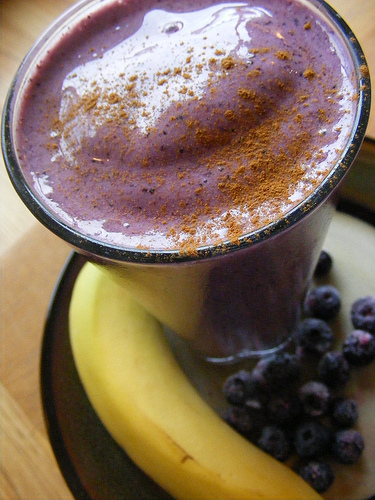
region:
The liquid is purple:
[8, 1, 357, 357]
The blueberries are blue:
[233, 257, 372, 481]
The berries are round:
[222, 250, 372, 488]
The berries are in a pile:
[223, 253, 371, 480]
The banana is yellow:
[65, 255, 317, 494]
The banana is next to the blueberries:
[69, 255, 364, 493]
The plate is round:
[49, 133, 370, 498]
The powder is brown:
[59, 40, 358, 238]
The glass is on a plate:
[6, 4, 359, 496]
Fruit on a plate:
[48, 157, 367, 492]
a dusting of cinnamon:
[186, 77, 297, 214]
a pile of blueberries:
[222, 352, 368, 493]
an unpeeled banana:
[64, 260, 310, 498]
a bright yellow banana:
[63, 258, 320, 499]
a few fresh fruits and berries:
[74, 260, 368, 497]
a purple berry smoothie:
[13, 2, 371, 352]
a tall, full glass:
[0, 0, 372, 356]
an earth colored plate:
[38, 201, 370, 497]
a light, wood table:
[1, 188, 64, 493]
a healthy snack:
[40, 31, 361, 486]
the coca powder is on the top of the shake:
[236, 154, 290, 202]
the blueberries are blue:
[256, 357, 306, 407]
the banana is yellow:
[117, 361, 168, 423]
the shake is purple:
[122, 33, 163, 64]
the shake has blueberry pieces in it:
[128, 174, 165, 200]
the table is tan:
[2, 389, 33, 437]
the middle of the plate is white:
[338, 226, 366, 262]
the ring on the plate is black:
[36, 408, 68, 444]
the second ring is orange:
[51, 385, 66, 425]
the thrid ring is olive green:
[84, 428, 115, 460]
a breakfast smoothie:
[47, 54, 320, 308]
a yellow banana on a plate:
[73, 270, 286, 498]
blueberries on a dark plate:
[215, 337, 371, 463]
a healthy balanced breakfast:
[19, 167, 362, 477]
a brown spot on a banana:
[153, 417, 204, 483]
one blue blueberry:
[307, 283, 344, 320]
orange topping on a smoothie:
[162, 122, 298, 196]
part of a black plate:
[32, 382, 91, 461]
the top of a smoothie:
[26, 98, 331, 264]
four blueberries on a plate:
[308, 290, 373, 359]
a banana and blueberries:
[64, 261, 366, 499]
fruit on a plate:
[57, 307, 372, 476]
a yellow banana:
[75, 310, 208, 497]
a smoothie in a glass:
[55, 15, 335, 371]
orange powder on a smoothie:
[96, 24, 340, 246]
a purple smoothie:
[35, 18, 321, 358]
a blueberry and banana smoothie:
[90, 23, 345, 368]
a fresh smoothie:
[63, 31, 341, 364]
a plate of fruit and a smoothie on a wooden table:
[8, 6, 374, 498]